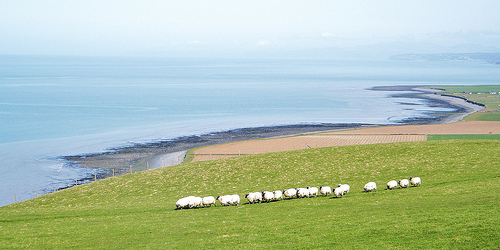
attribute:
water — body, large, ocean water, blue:
[5, 50, 499, 204]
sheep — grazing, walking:
[173, 173, 425, 210]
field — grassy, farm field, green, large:
[3, 87, 499, 245]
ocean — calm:
[6, 50, 497, 203]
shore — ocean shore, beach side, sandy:
[191, 120, 498, 165]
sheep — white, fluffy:
[364, 181, 378, 191]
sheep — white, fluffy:
[385, 176, 401, 192]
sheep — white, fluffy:
[398, 175, 412, 192]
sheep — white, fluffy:
[412, 176, 423, 188]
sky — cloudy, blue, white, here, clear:
[3, 0, 495, 68]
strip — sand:
[192, 121, 499, 163]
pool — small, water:
[446, 87, 499, 103]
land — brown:
[184, 119, 499, 168]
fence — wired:
[9, 154, 182, 205]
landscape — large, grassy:
[4, 87, 500, 244]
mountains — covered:
[393, 31, 499, 79]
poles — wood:
[9, 154, 185, 206]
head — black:
[386, 183, 394, 192]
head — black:
[398, 180, 403, 185]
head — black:
[409, 176, 416, 181]